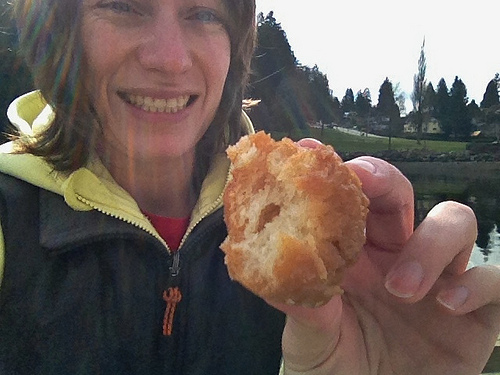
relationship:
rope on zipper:
[162, 287, 181, 334] [168, 249, 181, 291]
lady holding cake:
[1, 0, 499, 372] [218, 130, 371, 309]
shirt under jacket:
[139, 209, 192, 249] [0, 172, 287, 374]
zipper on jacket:
[168, 249, 181, 291] [0, 172, 287, 374]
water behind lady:
[340, 155, 497, 274] [1, 0, 499, 372]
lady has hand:
[1, 0, 499, 372] [264, 137, 497, 373]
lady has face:
[1, 0, 499, 372] [76, 0, 234, 164]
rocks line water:
[337, 149, 498, 161] [340, 155, 497, 274]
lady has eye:
[1, 0, 499, 372] [104, 0, 133, 14]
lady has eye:
[1, 0, 499, 372] [189, 8, 215, 24]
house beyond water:
[400, 100, 479, 137] [340, 155, 497, 274]